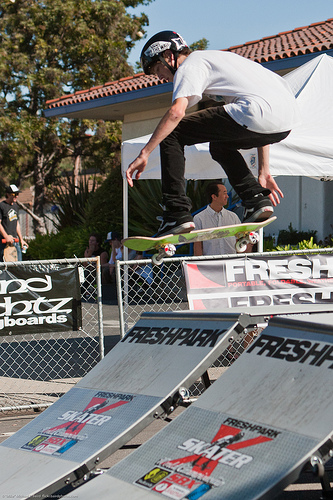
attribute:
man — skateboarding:
[125, 32, 296, 237]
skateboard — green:
[115, 215, 279, 264]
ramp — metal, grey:
[3, 311, 245, 499]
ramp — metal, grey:
[55, 311, 332, 499]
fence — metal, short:
[1, 249, 332, 412]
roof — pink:
[41, 18, 331, 119]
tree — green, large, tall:
[0, 0, 147, 242]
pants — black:
[161, 108, 292, 216]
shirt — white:
[172, 49, 299, 132]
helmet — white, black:
[142, 31, 187, 76]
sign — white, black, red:
[181, 252, 332, 316]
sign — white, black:
[0, 262, 84, 339]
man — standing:
[1, 183, 30, 262]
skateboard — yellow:
[1, 237, 22, 264]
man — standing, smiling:
[192, 182, 246, 257]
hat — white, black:
[5, 183, 21, 195]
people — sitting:
[83, 230, 162, 286]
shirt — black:
[0, 200, 20, 240]